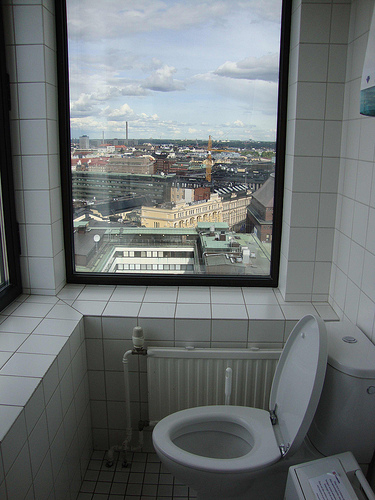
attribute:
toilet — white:
[151, 314, 374, 499]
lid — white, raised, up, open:
[266, 313, 330, 459]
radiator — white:
[104, 327, 284, 469]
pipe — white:
[122, 352, 132, 450]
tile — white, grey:
[78, 451, 191, 498]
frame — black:
[56, 0, 295, 287]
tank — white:
[311, 323, 374, 479]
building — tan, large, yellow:
[140, 196, 254, 226]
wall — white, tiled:
[332, 0, 374, 340]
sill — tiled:
[64, 285, 336, 319]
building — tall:
[124, 118, 132, 157]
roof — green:
[113, 226, 268, 272]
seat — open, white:
[152, 405, 283, 473]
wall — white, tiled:
[12, 2, 61, 300]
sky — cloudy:
[74, 0, 276, 120]